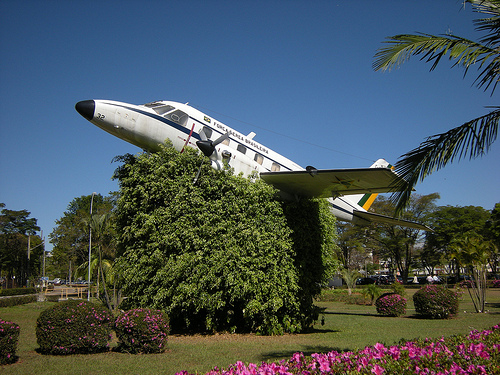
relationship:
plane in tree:
[73, 97, 431, 234] [116, 135, 340, 336]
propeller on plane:
[194, 126, 232, 189] [73, 97, 431, 234]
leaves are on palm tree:
[373, 3, 499, 236] [372, 1, 499, 234]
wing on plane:
[256, 164, 418, 195] [73, 97, 431, 234]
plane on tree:
[73, 97, 431, 234] [116, 135, 340, 336]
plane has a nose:
[73, 97, 431, 234] [73, 98, 97, 120]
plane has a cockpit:
[73, 97, 431, 234] [141, 94, 195, 154]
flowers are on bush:
[0, 318, 22, 366] [0, 317, 19, 363]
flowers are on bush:
[35, 299, 112, 353] [37, 299, 113, 355]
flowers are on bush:
[113, 306, 171, 353] [114, 306, 170, 354]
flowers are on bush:
[375, 290, 406, 316] [376, 290, 405, 316]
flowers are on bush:
[412, 282, 459, 318] [413, 281, 463, 316]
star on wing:
[328, 172, 357, 191] [256, 164, 418, 195]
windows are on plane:
[144, 100, 286, 173] [73, 97, 431, 234]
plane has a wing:
[73, 97, 431, 234] [256, 164, 418, 195]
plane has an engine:
[73, 97, 431, 234] [195, 138, 257, 176]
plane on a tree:
[73, 97, 431, 234] [116, 135, 340, 336]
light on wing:
[303, 163, 318, 178] [256, 164, 418, 195]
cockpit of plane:
[141, 94, 195, 154] [73, 97, 431, 234]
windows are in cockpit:
[144, 99, 189, 128] [141, 94, 195, 154]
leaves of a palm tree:
[373, 3, 499, 236] [372, 1, 499, 234]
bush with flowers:
[37, 299, 113, 355] [35, 299, 112, 353]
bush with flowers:
[0, 317, 19, 363] [0, 318, 22, 366]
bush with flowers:
[413, 281, 463, 316] [412, 282, 459, 318]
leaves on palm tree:
[373, 3, 499, 236] [372, 1, 499, 234]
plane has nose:
[73, 97, 431, 234] [73, 98, 97, 120]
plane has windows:
[73, 97, 431, 234] [144, 99, 189, 128]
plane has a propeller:
[73, 97, 431, 234] [194, 126, 232, 189]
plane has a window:
[73, 97, 431, 234] [144, 99, 189, 128]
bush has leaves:
[0, 317, 19, 363] [373, 3, 499, 236]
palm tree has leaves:
[372, 1, 499, 234] [373, 3, 499, 236]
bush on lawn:
[37, 299, 113, 355] [3, 281, 497, 373]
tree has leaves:
[116, 135, 340, 336] [111, 134, 342, 328]